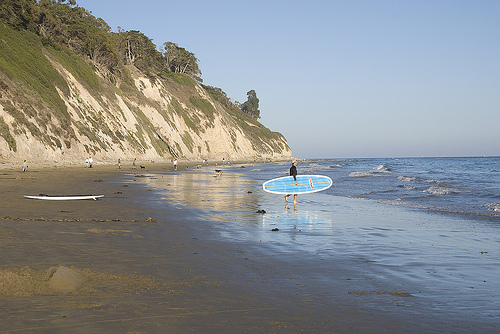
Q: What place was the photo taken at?
A: It was taken at the beach.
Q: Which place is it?
A: It is a beach.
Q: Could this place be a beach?
A: Yes, it is a beach.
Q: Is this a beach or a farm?
A: It is a beach.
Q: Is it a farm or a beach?
A: It is a beach.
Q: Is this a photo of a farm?
A: No, the picture is showing a beach.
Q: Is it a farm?
A: No, it is a beach.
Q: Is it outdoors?
A: Yes, it is outdoors.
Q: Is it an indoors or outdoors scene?
A: It is outdoors.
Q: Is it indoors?
A: No, it is outdoors.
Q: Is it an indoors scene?
A: No, it is outdoors.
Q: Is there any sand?
A: Yes, there is sand.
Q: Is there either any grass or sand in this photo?
A: Yes, there is sand.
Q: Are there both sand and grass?
A: Yes, there are both sand and grass.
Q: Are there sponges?
A: No, there are no sponges.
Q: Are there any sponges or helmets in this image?
A: No, there are no sponges or helmets.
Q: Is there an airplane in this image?
A: No, there are no airplanes.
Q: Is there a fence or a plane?
A: No, there are no airplanes or fences.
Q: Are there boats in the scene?
A: No, there are no boats.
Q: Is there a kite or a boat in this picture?
A: No, there are no boats or kites.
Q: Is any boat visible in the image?
A: No, there are no boats.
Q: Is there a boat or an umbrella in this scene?
A: No, there are no boats or umbrellas.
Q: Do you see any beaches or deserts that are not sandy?
A: No, there is a beach but it is sandy.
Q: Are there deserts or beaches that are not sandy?
A: No, there is a beach but it is sandy.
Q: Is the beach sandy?
A: Yes, the beach is sandy.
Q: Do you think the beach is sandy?
A: Yes, the beach is sandy.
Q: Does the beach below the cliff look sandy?
A: Yes, the beach is sandy.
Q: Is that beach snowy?
A: No, the beach is sandy.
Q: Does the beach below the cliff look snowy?
A: No, the beach is sandy.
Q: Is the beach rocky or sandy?
A: The beach is sandy.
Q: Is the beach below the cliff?
A: Yes, the beach is below the cliff.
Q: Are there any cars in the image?
A: No, there are no cars.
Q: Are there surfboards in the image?
A: Yes, there is a surfboard.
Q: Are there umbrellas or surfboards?
A: Yes, there is a surfboard.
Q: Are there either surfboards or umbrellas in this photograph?
A: Yes, there is a surfboard.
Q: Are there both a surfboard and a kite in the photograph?
A: No, there is a surfboard but no kites.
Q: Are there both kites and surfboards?
A: No, there is a surfboard but no kites.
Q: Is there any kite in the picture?
A: No, there are no kites.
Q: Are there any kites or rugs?
A: No, there are no kites or rugs.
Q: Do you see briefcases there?
A: No, there are no briefcases.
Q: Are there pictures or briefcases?
A: No, there are no briefcases or pictures.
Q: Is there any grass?
A: Yes, there is grass.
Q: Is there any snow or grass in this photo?
A: Yes, there is grass.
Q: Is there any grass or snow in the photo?
A: Yes, there is grass.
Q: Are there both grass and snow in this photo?
A: No, there is grass but no snow.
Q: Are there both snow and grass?
A: No, there is grass but no snow.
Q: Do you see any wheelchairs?
A: No, there are no wheelchairs.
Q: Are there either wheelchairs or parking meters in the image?
A: No, there are no wheelchairs or parking meters.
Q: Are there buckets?
A: No, there are no buckets.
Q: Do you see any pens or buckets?
A: No, there are no buckets or pens.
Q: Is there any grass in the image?
A: Yes, there is grass.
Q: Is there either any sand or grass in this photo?
A: Yes, there is grass.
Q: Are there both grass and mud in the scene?
A: No, there is grass but no mud.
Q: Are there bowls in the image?
A: No, there are no bowls.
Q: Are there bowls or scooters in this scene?
A: No, there are no bowls or scooters.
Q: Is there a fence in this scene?
A: No, there are no fences.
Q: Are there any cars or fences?
A: No, there are no fences or cars.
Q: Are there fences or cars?
A: No, there are no fences or cars.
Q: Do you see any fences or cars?
A: No, there are no fences or cars.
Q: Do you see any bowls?
A: No, there are no bowls.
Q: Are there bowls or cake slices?
A: No, there are no bowls or cake slices.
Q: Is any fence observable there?
A: No, there are no fences.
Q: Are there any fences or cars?
A: No, there are no fences or cars.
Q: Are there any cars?
A: No, there are no cars.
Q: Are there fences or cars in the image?
A: No, there are no cars or fences.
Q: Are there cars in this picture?
A: No, there are no cars.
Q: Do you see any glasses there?
A: No, there are no glasses.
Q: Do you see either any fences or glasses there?
A: No, there are no glasses or fences.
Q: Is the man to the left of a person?
A: No, the man is to the right of a person.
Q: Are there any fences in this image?
A: No, there are no fences.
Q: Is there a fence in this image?
A: No, there are no fences.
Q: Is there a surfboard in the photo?
A: Yes, there is a surfboard.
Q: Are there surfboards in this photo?
A: Yes, there is a surfboard.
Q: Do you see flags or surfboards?
A: Yes, there is a surfboard.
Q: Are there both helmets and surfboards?
A: No, there is a surfboard but no helmets.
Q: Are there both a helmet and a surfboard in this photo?
A: No, there is a surfboard but no helmets.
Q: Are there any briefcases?
A: No, there are no briefcases.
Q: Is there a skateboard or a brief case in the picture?
A: No, there are no briefcases or skateboards.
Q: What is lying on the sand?
A: The surfboard is lying on the sand.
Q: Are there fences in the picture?
A: No, there are no fences.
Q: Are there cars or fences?
A: No, there are no fences or cars.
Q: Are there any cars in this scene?
A: No, there are no cars.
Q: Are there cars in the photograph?
A: No, there are no cars.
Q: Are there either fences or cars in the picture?
A: No, there are no cars or fences.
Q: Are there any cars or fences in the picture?
A: No, there are no cars or fences.